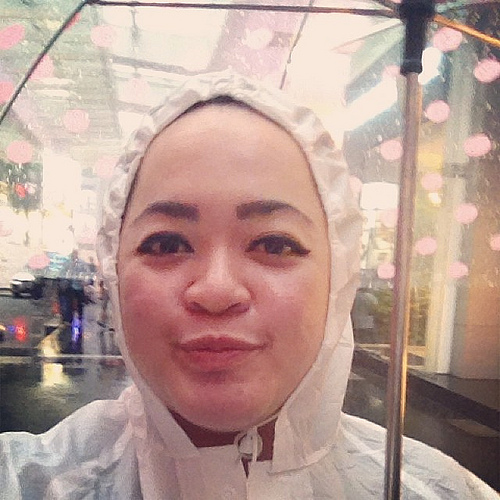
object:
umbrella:
[0, 0, 500, 500]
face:
[115, 107, 329, 435]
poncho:
[0, 67, 500, 499]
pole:
[381, 70, 421, 500]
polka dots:
[461, 132, 492, 162]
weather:
[0, 0, 500, 274]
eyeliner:
[248, 234, 309, 254]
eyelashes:
[245, 235, 311, 254]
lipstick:
[194, 353, 235, 360]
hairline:
[181, 95, 262, 111]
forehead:
[130, 105, 319, 195]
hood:
[93, 70, 360, 478]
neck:
[150, 412, 291, 461]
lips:
[166, 324, 274, 368]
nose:
[176, 267, 263, 318]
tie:
[230, 411, 280, 471]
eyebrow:
[233, 198, 317, 233]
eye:
[134, 227, 195, 257]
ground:
[0, 292, 500, 493]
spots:
[5, 135, 34, 168]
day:
[0, 0, 490, 500]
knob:
[395, 0, 433, 78]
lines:
[34, 342, 125, 376]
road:
[0, 308, 130, 437]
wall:
[451, 0, 500, 380]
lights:
[0, 151, 83, 266]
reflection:
[35, 321, 68, 390]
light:
[110, 65, 173, 103]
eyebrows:
[124, 198, 203, 226]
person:
[0, 76, 500, 500]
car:
[9, 255, 68, 300]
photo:
[0, 0, 500, 500]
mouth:
[156, 326, 274, 369]